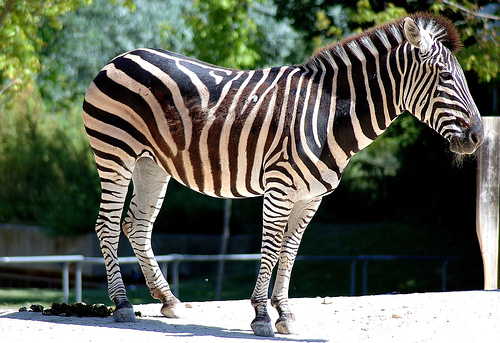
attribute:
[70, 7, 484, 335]
zebra — standing, alone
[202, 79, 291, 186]
stripes — black, white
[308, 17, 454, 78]
mane — striped, black, white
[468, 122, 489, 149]
nose — black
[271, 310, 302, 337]
hoof — gray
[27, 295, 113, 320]
droppings — fresh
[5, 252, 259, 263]
hand railing — blueish, gray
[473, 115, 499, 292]
pole — white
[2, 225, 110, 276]
fence — metal